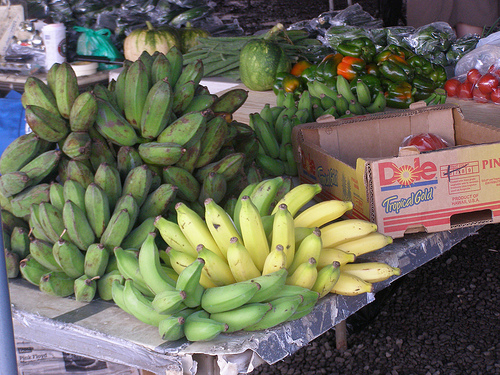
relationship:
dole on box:
[378, 156, 438, 188] [292, 101, 499, 238]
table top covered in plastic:
[16, 288, 127, 352] [138, 334, 159, 361]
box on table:
[301, 93, 489, 260] [76, 277, 351, 364]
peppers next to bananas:
[351, 40, 451, 102] [298, 76, 370, 113]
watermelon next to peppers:
[238, 39, 290, 93] [273, 37, 448, 107]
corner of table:
[160, 348, 272, 373] [12, 79, 490, 373]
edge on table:
[13, 310, 216, 372] [9, 222, 484, 374]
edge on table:
[208, 328, 321, 373] [9, 222, 484, 374]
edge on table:
[416, 227, 492, 257] [9, 222, 484, 374]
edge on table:
[373, 253, 411, 287] [9, 222, 484, 374]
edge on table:
[303, 308, 345, 335] [9, 222, 484, 374]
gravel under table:
[252, 236, 495, 371] [3, 5, 498, 370]